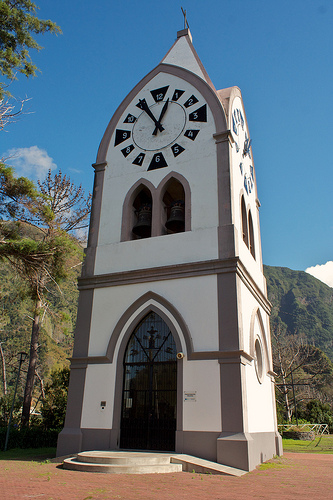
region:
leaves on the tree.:
[19, 15, 27, 32]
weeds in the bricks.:
[38, 472, 51, 481]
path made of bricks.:
[309, 454, 329, 460]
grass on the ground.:
[290, 444, 301, 452]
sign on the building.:
[182, 387, 199, 401]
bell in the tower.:
[165, 186, 181, 233]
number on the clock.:
[152, 150, 164, 165]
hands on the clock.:
[134, 94, 173, 133]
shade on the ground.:
[15, 445, 42, 460]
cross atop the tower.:
[172, 5, 190, 28]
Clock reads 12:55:
[109, 81, 208, 168]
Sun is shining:
[1, 1, 332, 284]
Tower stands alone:
[52, 6, 284, 477]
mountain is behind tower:
[259, 263, 332, 362]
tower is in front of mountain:
[54, 8, 285, 478]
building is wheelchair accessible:
[60, 448, 249, 479]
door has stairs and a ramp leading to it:
[61, 300, 246, 477]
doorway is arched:
[111, 303, 181, 450]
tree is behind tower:
[268, 326, 308, 424]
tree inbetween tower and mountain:
[264, 324, 308, 429]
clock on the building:
[105, 93, 205, 165]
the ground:
[137, 481, 229, 496]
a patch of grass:
[259, 457, 285, 472]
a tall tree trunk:
[20, 306, 43, 437]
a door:
[127, 331, 172, 448]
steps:
[88, 444, 143, 473]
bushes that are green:
[297, 348, 328, 373]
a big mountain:
[274, 268, 318, 321]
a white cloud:
[304, 262, 330, 274]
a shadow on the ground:
[16, 442, 44, 461]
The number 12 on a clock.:
[156, 92, 163, 101]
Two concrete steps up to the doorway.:
[62, 450, 181, 470]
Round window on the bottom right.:
[254, 337, 263, 379]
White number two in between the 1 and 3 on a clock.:
[187, 97, 194, 105]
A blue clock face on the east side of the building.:
[230, 106, 256, 195]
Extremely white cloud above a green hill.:
[305, 258, 332, 285]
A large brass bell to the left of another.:
[129, 205, 152, 237]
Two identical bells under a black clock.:
[128, 197, 184, 230]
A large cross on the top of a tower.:
[179, 8, 190, 32]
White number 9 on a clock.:
[122, 130, 129, 138]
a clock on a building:
[60, 20, 316, 228]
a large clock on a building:
[77, 38, 330, 287]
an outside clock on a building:
[103, 75, 282, 231]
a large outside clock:
[75, 50, 236, 202]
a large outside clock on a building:
[57, 32, 330, 183]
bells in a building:
[69, 166, 275, 273]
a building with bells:
[100, 153, 244, 292]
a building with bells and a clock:
[83, 31, 327, 266]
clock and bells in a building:
[100, 48, 313, 317]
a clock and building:
[83, 60, 311, 328]